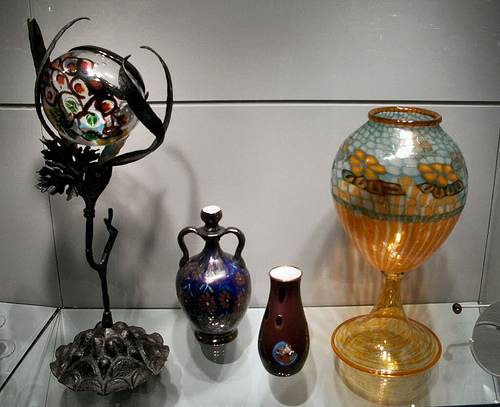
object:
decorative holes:
[275, 315, 284, 327]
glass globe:
[38, 48, 146, 147]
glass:
[327, 104, 471, 380]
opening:
[368, 105, 441, 122]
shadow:
[266, 348, 318, 407]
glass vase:
[329, 104, 471, 379]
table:
[0, 303, 500, 407]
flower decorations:
[417, 162, 459, 189]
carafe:
[174, 203, 253, 346]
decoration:
[272, 340, 299, 366]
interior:
[269, 266, 302, 281]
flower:
[348, 148, 388, 181]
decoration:
[40, 48, 147, 147]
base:
[48, 319, 172, 397]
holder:
[25, 14, 175, 397]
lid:
[202, 205, 221, 215]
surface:
[0, 300, 499, 407]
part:
[272, 340, 299, 367]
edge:
[271, 374, 297, 378]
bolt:
[451, 302, 491, 315]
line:
[0, 100, 500, 110]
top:
[268, 264, 304, 283]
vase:
[256, 263, 312, 378]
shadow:
[314, 216, 383, 285]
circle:
[271, 340, 298, 367]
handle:
[176, 225, 198, 269]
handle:
[225, 226, 247, 270]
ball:
[39, 47, 149, 148]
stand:
[25, 14, 175, 397]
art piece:
[25, 15, 175, 398]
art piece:
[174, 204, 253, 347]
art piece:
[257, 263, 312, 378]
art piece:
[328, 103, 470, 379]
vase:
[174, 203, 253, 346]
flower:
[197, 291, 218, 314]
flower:
[234, 270, 247, 287]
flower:
[219, 291, 231, 309]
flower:
[180, 292, 193, 308]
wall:
[1, 0, 500, 308]